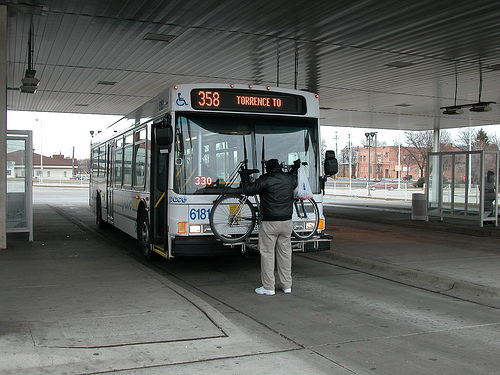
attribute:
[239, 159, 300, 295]
person — standing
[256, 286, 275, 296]
shoe — white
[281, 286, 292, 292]
shoe — white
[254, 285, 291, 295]
shoes — white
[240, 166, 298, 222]
coat — black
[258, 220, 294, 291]
pants — brown, tan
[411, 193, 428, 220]
trash can — standing, large, outdoors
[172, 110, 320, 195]
windshield — big, large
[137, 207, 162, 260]
tire — black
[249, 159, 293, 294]
person — standing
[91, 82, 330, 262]
bus — white, large